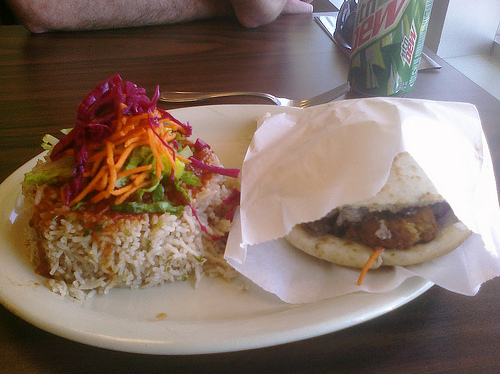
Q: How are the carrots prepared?
A: They are thinly sliced.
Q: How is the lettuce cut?
A: Thinly sliced.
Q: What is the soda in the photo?
A: Mountain Dew.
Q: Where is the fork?
A: Above plate.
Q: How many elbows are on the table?
A: 2.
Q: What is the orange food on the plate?
A: Carrot.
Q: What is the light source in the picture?
A: Sun.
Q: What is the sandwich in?
A: White wrapper.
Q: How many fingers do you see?
A: 1.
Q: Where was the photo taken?
A: Inside somewhere.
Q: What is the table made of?
A: Wood.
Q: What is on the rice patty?
A: Vegetable.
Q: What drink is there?
A: Mountain Dew.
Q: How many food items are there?
A: Two.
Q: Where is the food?
A: On the plate.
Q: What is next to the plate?
A: A fork.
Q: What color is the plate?
A: White.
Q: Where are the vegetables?
A: On the rice patty.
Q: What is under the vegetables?
A: A rice patty.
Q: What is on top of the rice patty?
A: Vegetables.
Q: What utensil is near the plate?
A: A fork.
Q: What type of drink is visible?
A: Soda.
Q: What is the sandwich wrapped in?
A: A white bag.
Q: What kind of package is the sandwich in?
A: A paper bag.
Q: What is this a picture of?
A: A plate with food on it.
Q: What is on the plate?
A: A sandwich.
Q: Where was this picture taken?
A: A restaurant.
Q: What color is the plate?
A: White.